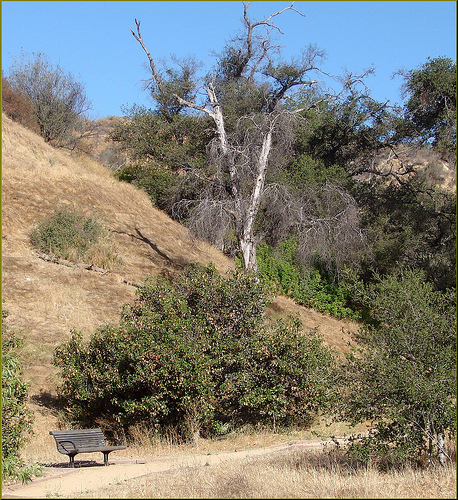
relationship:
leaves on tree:
[268, 156, 343, 201] [263, 103, 375, 324]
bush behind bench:
[103, 172, 297, 493] [26, 379, 172, 498]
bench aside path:
[47, 426, 126, 469] [20, 455, 217, 498]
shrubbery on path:
[52, 263, 345, 440] [6, 434, 382, 494]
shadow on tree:
[110, 222, 181, 269] [172, 82, 333, 288]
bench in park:
[47, 426, 126, 469] [0, 52, 452, 492]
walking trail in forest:
[28, 392, 389, 493] [109, 61, 448, 441]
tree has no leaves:
[161, 74, 340, 283] [171, 200, 186, 224]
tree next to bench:
[91, 284, 341, 431] [49, 423, 120, 464]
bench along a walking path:
[47, 426, 126, 469] [16, 427, 380, 498]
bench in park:
[47, 426, 126, 469] [2, 9, 453, 496]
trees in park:
[60, 260, 329, 435] [2, 9, 453, 496]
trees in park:
[325, 265, 455, 495] [2, 9, 453, 496]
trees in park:
[123, 3, 455, 341] [2, 9, 453, 496]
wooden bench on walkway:
[48, 426, 127, 464] [12, 419, 376, 498]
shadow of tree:
[110, 222, 181, 269] [175, 42, 278, 303]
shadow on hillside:
[110, 222, 181, 269] [4, 102, 380, 455]